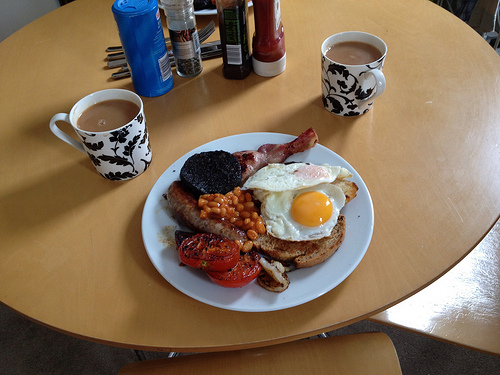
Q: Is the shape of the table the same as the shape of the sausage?
A: Yes, both the table and the sausage are round.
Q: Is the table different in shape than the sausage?
A: No, both the table and the sausage are round.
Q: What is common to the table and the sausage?
A: The shape, both the table and the sausage are round.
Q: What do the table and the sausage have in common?
A: The shape, both the table and the sausage are round.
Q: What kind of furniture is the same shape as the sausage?
A: The table is the same shape as the sausage.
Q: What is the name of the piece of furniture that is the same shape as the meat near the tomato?
A: The piece of furniture is a table.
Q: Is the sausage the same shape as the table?
A: Yes, both the sausage and the table are round.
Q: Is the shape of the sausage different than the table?
A: No, both the sausage and the table are round.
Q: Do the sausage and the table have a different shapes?
A: No, both the sausage and the table are round.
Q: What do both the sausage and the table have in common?
A: The shape, both the sausage and the table are round.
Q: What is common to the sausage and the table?
A: The shape, both the sausage and the table are round.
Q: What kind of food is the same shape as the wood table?
A: The sausage is the same shape as the table.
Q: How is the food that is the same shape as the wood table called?
A: The food is a sausage.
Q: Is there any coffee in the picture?
A: Yes, there is coffee.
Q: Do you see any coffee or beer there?
A: Yes, there is coffee.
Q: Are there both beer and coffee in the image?
A: No, there is coffee but no beer.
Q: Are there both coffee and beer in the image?
A: No, there is coffee but no beer.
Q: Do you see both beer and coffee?
A: No, there is coffee but no beer.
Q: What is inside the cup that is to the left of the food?
A: The coffee is inside the cup.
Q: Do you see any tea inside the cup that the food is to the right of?
A: No, there is coffee inside the cup.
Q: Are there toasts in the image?
A: Yes, there is a toast.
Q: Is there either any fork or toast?
A: Yes, there is a toast.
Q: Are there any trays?
A: No, there are no trays.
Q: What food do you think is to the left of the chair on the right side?
A: The food is a toast.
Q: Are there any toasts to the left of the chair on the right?
A: Yes, there is a toast to the left of the chair.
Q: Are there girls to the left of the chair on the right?
A: No, there is a toast to the left of the chair.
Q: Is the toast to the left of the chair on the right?
A: Yes, the toast is to the left of the chair.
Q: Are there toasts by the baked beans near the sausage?
A: Yes, there is a toast by the beans.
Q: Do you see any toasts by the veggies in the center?
A: Yes, there is a toast by the beans.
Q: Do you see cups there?
A: Yes, there is a cup.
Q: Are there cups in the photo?
A: Yes, there is a cup.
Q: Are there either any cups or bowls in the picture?
A: Yes, there is a cup.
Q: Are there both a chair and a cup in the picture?
A: Yes, there are both a cup and a chair.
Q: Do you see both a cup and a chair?
A: Yes, there are both a cup and a chair.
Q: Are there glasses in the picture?
A: No, there are no glasses.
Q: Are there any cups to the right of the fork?
A: Yes, there is a cup to the right of the fork.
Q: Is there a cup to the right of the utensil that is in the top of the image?
A: Yes, there is a cup to the right of the fork.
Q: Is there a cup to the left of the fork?
A: No, the cup is to the right of the fork.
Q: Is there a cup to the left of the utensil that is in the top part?
A: No, the cup is to the right of the fork.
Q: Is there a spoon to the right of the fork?
A: No, there is a cup to the right of the fork.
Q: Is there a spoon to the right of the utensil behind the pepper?
A: No, there is a cup to the right of the fork.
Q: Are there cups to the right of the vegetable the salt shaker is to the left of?
A: Yes, there is a cup to the right of the pepper.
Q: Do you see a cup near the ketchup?
A: Yes, there is a cup near the ketchup.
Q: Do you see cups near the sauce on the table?
A: Yes, there is a cup near the ketchup.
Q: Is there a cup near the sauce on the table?
A: Yes, there is a cup near the ketchup.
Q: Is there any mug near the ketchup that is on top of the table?
A: No, there is a cup near the ketchup.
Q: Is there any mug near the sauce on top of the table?
A: No, there is a cup near the ketchup.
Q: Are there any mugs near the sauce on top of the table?
A: No, there is a cup near the ketchup.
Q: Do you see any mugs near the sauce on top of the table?
A: No, there is a cup near the ketchup.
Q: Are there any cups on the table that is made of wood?
A: Yes, there is a cup on the table.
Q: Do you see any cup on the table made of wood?
A: Yes, there is a cup on the table.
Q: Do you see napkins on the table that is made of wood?
A: No, there is a cup on the table.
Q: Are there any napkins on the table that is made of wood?
A: No, there is a cup on the table.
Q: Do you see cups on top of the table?
A: Yes, there is a cup on top of the table.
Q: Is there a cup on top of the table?
A: Yes, there is a cup on top of the table.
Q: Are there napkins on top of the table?
A: No, there is a cup on top of the table.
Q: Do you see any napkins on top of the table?
A: No, there is a cup on top of the table.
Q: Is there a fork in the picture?
A: Yes, there is a fork.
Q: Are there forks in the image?
A: Yes, there is a fork.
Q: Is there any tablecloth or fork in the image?
A: Yes, there is a fork.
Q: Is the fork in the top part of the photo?
A: Yes, the fork is in the top of the image.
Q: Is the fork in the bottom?
A: No, the fork is in the top of the image.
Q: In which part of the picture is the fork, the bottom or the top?
A: The fork is in the top of the image.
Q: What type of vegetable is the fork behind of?
A: The fork is behind the pepper.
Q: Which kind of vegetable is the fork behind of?
A: The fork is behind the pepper.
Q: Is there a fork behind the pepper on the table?
A: Yes, there is a fork behind the pepper.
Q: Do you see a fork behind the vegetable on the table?
A: Yes, there is a fork behind the pepper.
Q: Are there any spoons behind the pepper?
A: No, there is a fork behind the pepper.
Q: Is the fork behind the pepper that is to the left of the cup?
A: Yes, the fork is behind the pepper.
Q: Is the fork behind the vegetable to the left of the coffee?
A: Yes, the fork is behind the pepper.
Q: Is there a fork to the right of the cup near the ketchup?
A: No, the fork is to the left of the cup.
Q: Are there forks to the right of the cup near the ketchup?
A: No, the fork is to the left of the cup.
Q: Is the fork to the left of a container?
A: No, the fork is to the left of the cup.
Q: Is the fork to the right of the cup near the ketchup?
A: No, the fork is to the left of the cup.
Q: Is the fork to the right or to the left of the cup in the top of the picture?
A: The fork is to the left of the cup.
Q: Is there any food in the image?
A: Yes, there is food.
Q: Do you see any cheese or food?
A: Yes, there is food.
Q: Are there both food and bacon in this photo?
A: Yes, there are both food and bacon.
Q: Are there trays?
A: No, there are no trays.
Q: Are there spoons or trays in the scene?
A: No, there are no trays or spoons.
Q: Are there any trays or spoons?
A: No, there are no trays or spoons.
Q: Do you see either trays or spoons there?
A: No, there are no trays or spoons.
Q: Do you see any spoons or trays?
A: No, there are no trays or spoons.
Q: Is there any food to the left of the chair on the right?
A: Yes, there is food to the left of the chair.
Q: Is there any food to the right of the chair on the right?
A: No, the food is to the left of the chair.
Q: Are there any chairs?
A: Yes, there is a chair.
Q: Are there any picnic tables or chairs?
A: Yes, there is a chair.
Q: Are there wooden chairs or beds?
A: Yes, there is a wood chair.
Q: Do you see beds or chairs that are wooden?
A: Yes, the chair is wooden.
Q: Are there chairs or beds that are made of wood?
A: Yes, the chair is made of wood.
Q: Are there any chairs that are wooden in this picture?
A: Yes, there is a wood chair.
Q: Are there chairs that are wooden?
A: Yes, there is a chair that is wooden.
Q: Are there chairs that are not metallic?
A: Yes, there is a wooden chair.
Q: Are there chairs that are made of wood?
A: Yes, there is a chair that is made of wood.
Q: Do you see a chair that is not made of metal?
A: Yes, there is a chair that is made of wood.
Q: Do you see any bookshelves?
A: No, there are no bookshelves.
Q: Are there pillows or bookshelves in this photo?
A: No, there are no bookshelves or pillows.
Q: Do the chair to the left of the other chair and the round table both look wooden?
A: Yes, both the chair and the table are wooden.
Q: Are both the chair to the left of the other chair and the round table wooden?
A: Yes, both the chair and the table are wooden.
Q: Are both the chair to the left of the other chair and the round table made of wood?
A: Yes, both the chair and the table are made of wood.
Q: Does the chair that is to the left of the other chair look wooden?
A: Yes, the chair is wooden.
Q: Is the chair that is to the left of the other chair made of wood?
A: Yes, the chair is made of wood.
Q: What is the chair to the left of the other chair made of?
A: The chair is made of wood.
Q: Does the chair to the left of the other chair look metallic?
A: No, the chair is wooden.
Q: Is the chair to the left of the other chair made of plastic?
A: No, the chair is made of wood.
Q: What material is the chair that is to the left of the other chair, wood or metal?
A: The chair is made of wood.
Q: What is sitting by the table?
A: The chair is sitting by the table.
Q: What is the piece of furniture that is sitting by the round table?
A: The piece of furniture is a chair.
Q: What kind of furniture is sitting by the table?
A: The piece of furniture is a chair.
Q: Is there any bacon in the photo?
A: Yes, there is bacon.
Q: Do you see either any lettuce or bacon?
A: Yes, there is bacon.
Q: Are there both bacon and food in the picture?
A: Yes, there are both bacon and food.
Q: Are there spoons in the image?
A: No, there are no spoons.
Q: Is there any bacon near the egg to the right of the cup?
A: Yes, there is bacon near the egg.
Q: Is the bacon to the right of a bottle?
A: No, the bacon is to the right of the cup.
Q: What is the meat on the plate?
A: The meat is bacon.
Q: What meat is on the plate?
A: The meat is bacon.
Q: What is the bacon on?
A: The bacon is on the plate.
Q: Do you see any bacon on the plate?
A: Yes, there is bacon on the plate.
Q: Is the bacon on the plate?
A: Yes, the bacon is on the plate.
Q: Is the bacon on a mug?
A: No, the bacon is on the plate.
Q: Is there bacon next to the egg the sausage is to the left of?
A: Yes, there is bacon next to the egg.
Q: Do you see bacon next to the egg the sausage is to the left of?
A: Yes, there is bacon next to the egg.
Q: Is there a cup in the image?
A: Yes, there is a cup.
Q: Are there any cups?
A: Yes, there is a cup.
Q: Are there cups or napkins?
A: Yes, there is a cup.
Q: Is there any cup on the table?
A: Yes, there is a cup on the table.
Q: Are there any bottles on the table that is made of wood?
A: No, there is a cup on the table.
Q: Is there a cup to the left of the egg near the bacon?
A: Yes, there is a cup to the left of the egg.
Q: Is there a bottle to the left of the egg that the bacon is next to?
A: No, there is a cup to the left of the egg.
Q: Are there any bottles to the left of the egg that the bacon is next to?
A: No, there is a cup to the left of the egg.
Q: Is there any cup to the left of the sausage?
A: Yes, there is a cup to the left of the sausage.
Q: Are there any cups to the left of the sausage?
A: Yes, there is a cup to the left of the sausage.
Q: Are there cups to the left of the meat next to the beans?
A: Yes, there is a cup to the left of the sausage.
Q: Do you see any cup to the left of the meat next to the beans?
A: Yes, there is a cup to the left of the sausage.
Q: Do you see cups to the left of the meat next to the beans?
A: Yes, there is a cup to the left of the sausage.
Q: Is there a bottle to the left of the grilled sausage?
A: No, there is a cup to the left of the sausage.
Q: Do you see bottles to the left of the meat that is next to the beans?
A: No, there is a cup to the left of the sausage.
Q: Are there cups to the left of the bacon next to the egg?
A: Yes, there is a cup to the left of the bacon.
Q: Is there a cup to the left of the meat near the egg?
A: Yes, there is a cup to the left of the bacon.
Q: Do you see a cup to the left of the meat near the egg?
A: Yes, there is a cup to the left of the bacon.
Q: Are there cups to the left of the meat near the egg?
A: Yes, there is a cup to the left of the bacon.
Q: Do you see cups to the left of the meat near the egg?
A: Yes, there is a cup to the left of the bacon.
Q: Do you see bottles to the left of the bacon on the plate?
A: No, there is a cup to the left of the bacon.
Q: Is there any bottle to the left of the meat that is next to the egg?
A: No, there is a cup to the left of the bacon.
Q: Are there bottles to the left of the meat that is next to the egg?
A: No, there is a cup to the left of the bacon.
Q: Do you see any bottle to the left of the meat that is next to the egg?
A: No, there is a cup to the left of the bacon.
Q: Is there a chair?
A: Yes, there is a chair.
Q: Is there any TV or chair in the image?
A: Yes, there is a chair.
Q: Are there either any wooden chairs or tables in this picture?
A: Yes, there is a wood chair.